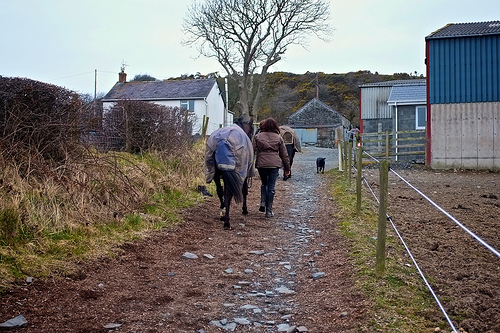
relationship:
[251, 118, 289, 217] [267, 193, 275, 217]
woman wears black boots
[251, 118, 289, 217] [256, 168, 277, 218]
woman wears pants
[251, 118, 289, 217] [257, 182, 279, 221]
woman wears black boots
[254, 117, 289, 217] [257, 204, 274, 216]
woman wearing shoes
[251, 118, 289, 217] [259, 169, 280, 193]
woman wearing blue jeans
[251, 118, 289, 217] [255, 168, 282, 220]
woman wearing pants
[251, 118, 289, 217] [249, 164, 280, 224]
woman wearing blue jeans